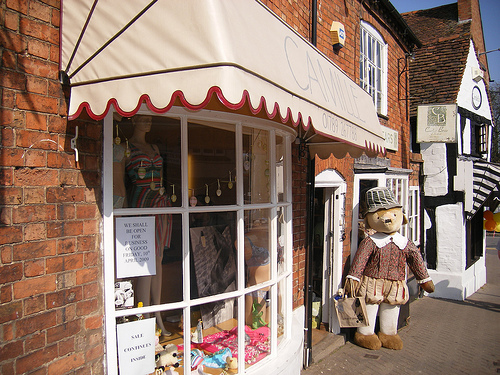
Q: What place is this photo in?
A: It is at the store.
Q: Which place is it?
A: It is a store.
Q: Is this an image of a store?
A: Yes, it is showing a store.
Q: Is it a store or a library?
A: It is a store.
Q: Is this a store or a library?
A: It is a store.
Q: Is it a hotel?
A: No, it is a store.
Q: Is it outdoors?
A: Yes, it is outdoors.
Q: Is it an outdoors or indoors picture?
A: It is outdoors.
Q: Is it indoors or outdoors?
A: It is outdoors.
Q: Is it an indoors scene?
A: No, it is outdoors.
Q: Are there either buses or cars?
A: No, there are no cars or buses.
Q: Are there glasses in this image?
A: No, there are no glasses.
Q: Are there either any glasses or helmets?
A: No, there are no glasses or helmets.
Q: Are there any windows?
A: Yes, there is a window.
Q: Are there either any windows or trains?
A: Yes, there is a window.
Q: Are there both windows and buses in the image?
A: No, there is a window but no buses.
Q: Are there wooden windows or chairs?
A: Yes, there is a wood window.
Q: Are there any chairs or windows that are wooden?
A: Yes, the window is wooden.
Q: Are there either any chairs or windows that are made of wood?
A: Yes, the window is made of wood.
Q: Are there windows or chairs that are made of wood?
A: Yes, the window is made of wood.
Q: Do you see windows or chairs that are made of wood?
A: Yes, the window is made of wood.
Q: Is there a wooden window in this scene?
A: Yes, there is a wood window.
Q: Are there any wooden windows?
A: Yes, there is a wood window.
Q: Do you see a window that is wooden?
A: Yes, there is a window that is wooden.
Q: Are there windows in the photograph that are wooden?
A: Yes, there is a window that is wooden.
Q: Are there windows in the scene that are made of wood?
A: Yes, there is a window that is made of wood.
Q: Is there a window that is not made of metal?
A: Yes, there is a window that is made of wood.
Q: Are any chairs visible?
A: No, there are no chairs.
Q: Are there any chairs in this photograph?
A: No, there are no chairs.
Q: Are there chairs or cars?
A: No, there are no chairs or cars.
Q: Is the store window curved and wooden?
A: Yes, the window is curved and wooden.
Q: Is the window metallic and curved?
A: No, the window is curved but wooden.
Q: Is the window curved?
A: Yes, the window is curved.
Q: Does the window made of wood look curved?
A: Yes, the window is curved.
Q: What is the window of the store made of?
A: The window is made of wood.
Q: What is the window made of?
A: The window is made of wood.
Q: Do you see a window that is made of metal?
A: No, there is a window but it is made of wood.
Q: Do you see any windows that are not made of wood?
A: No, there is a window but it is made of wood.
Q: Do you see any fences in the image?
A: No, there are no fences.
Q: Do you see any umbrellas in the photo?
A: No, there are no umbrellas.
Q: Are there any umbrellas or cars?
A: No, there are no umbrellas or cars.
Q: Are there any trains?
A: No, there are no trains.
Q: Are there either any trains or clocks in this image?
A: No, there are no trains or clocks.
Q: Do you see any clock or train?
A: No, there are no trains or clocks.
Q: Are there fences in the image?
A: No, there are no fences.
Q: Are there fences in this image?
A: No, there are no fences.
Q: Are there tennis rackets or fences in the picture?
A: No, there are no fences or tennis rackets.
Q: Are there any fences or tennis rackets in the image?
A: No, there are no fences or tennis rackets.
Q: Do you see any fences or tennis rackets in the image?
A: No, there are no fences or tennis rackets.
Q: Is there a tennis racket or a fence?
A: No, there are no fences or rackets.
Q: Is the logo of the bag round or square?
A: The logo is round.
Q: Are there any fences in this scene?
A: No, there are no fences.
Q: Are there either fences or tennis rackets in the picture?
A: No, there are no fences or tennis rackets.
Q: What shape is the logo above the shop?
A: The logo is round.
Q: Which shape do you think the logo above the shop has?
A: The logo has round shape.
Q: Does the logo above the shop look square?
A: No, the logo is round.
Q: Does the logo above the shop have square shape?
A: No, the logo is round.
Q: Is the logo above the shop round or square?
A: The logo is round.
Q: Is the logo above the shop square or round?
A: The logo is round.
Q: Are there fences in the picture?
A: No, there are no fences.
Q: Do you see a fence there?
A: No, there are no fences.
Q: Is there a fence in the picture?
A: No, there are no fences.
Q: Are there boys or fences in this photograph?
A: No, there are no fences or boys.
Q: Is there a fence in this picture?
A: No, there are no fences.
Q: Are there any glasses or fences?
A: No, there are no fences or glasses.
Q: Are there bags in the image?
A: Yes, there is a bag.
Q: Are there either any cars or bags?
A: Yes, there is a bag.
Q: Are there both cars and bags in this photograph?
A: No, there is a bag but no cars.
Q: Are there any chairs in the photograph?
A: No, there are no chairs.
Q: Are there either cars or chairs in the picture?
A: No, there are no chairs or cars.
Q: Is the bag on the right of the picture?
A: Yes, the bag is on the right of the image.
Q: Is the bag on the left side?
A: No, the bag is on the right of the image.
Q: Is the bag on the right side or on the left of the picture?
A: The bag is on the right of the image.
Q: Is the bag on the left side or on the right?
A: The bag is on the right of the image.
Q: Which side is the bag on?
A: The bag is on the right of the image.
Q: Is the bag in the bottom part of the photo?
A: Yes, the bag is in the bottom of the image.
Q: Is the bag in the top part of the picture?
A: No, the bag is in the bottom of the image.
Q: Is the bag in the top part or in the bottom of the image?
A: The bag is in the bottom of the image.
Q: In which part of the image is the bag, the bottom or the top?
A: The bag is in the bottom of the image.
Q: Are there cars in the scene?
A: No, there are no cars.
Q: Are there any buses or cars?
A: No, there are no cars or buses.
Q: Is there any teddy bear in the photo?
A: Yes, there is a teddy bear.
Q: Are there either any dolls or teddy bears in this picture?
A: Yes, there is a teddy bear.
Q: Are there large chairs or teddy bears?
A: Yes, there is a large teddy bear.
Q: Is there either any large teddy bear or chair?
A: Yes, there is a large teddy bear.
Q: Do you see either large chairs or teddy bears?
A: Yes, there is a large teddy bear.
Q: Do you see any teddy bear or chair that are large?
A: Yes, the teddy bear is large.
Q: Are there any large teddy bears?
A: Yes, there is a large teddy bear.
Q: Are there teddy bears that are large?
A: Yes, there is a teddy bear that is large.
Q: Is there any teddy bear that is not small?
A: Yes, there is a large teddy bear.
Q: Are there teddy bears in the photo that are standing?
A: Yes, there is a teddy bear that is standing.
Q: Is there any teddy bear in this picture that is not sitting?
A: Yes, there is a teddy bear that is standing.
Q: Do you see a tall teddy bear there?
A: Yes, there is a tall teddy bear.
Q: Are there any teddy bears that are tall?
A: Yes, there is a teddy bear that is tall.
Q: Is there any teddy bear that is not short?
A: Yes, there is a tall teddy bear.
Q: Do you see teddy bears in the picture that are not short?
A: Yes, there is a tall teddy bear.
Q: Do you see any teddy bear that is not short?
A: Yes, there is a tall teddy bear.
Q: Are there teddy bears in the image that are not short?
A: Yes, there is a tall teddy bear.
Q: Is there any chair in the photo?
A: No, there are no chairs.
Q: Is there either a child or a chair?
A: No, there are no chairs or children.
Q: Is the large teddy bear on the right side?
A: Yes, the teddy bear is on the right of the image.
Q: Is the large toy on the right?
A: Yes, the teddy bear is on the right of the image.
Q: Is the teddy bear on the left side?
A: No, the teddy bear is on the right of the image.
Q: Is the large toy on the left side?
A: No, the teddy bear is on the right of the image.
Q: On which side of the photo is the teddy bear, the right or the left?
A: The teddy bear is on the right of the image.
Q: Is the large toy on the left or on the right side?
A: The teddy bear is on the right of the image.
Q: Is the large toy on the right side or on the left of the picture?
A: The teddy bear is on the right of the image.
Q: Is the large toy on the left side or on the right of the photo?
A: The teddy bear is on the right of the image.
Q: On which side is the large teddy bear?
A: The teddy bear is on the right of the image.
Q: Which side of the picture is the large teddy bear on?
A: The teddy bear is on the right of the image.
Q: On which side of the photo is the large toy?
A: The teddy bear is on the right of the image.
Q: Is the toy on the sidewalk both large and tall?
A: Yes, the teddy bear is large and tall.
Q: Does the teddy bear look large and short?
A: No, the teddy bear is large but tall.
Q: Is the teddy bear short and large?
A: No, the teddy bear is large but tall.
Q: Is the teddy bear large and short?
A: No, the teddy bear is large but tall.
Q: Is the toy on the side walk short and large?
A: No, the teddy bear is large but tall.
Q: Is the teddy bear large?
A: Yes, the teddy bear is large.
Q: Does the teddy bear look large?
A: Yes, the teddy bear is large.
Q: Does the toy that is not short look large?
A: Yes, the teddy bear is large.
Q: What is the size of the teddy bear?
A: The teddy bear is large.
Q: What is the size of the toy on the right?
A: The teddy bear is large.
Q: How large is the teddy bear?
A: The teddy bear is large.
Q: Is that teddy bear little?
A: No, the teddy bear is large.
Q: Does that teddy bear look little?
A: No, the teddy bear is large.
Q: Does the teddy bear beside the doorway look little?
A: No, the teddy bear is large.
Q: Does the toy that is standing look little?
A: No, the teddy bear is large.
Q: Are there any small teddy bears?
A: No, there is a teddy bear but it is large.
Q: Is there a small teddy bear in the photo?
A: No, there is a teddy bear but it is large.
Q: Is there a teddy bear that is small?
A: No, there is a teddy bear but it is large.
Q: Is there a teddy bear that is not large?
A: No, there is a teddy bear but it is large.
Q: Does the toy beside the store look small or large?
A: The teddy bear is large.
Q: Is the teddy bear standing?
A: Yes, the teddy bear is standing.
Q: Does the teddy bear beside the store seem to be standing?
A: Yes, the teddy bear is standing.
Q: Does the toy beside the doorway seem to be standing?
A: Yes, the teddy bear is standing.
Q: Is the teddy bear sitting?
A: No, the teddy bear is standing.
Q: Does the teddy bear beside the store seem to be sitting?
A: No, the teddy bear is standing.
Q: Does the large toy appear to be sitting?
A: No, the teddy bear is standing.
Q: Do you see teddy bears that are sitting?
A: No, there is a teddy bear but it is standing.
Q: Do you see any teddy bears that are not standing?
A: No, there is a teddy bear but it is standing.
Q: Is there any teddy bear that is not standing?
A: No, there is a teddy bear but it is standing.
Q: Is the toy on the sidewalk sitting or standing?
A: The teddy bear is standing.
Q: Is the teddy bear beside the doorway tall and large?
A: Yes, the teddy bear is tall and large.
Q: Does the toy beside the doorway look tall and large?
A: Yes, the teddy bear is tall and large.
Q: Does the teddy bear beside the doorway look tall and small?
A: No, the teddy bear is tall but large.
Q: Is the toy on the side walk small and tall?
A: No, the teddy bear is tall but large.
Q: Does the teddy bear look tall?
A: Yes, the teddy bear is tall.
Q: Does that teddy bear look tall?
A: Yes, the teddy bear is tall.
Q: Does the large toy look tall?
A: Yes, the teddy bear is tall.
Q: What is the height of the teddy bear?
A: The teddy bear is tall.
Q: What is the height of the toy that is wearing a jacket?
A: The teddy bear is tall.